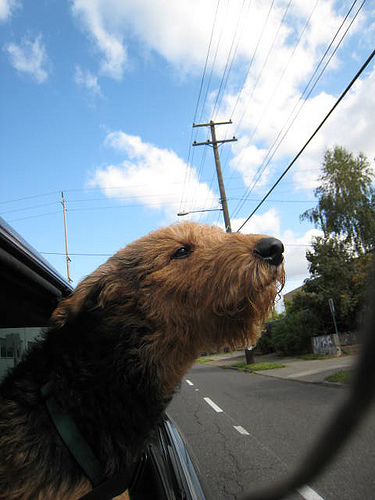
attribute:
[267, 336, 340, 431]
concrete — white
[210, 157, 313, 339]
post — tall, wooden, power line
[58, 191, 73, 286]
post — wooden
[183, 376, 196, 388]
line — white